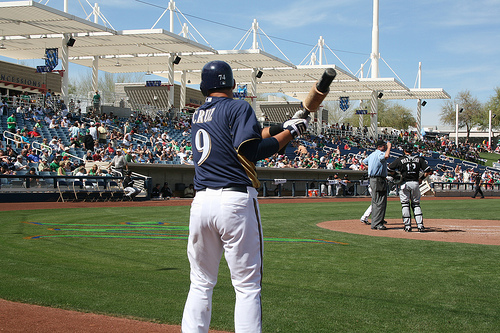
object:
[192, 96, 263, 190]
shirt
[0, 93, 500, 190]
people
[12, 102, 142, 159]
seats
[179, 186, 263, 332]
pants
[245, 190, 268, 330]
line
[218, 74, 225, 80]
number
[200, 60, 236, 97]
helmet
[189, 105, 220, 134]
lettering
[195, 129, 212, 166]
number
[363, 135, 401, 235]
man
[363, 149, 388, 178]
shirt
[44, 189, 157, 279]
grass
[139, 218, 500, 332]
dirt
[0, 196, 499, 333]
field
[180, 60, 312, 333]
player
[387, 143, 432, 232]
catcher